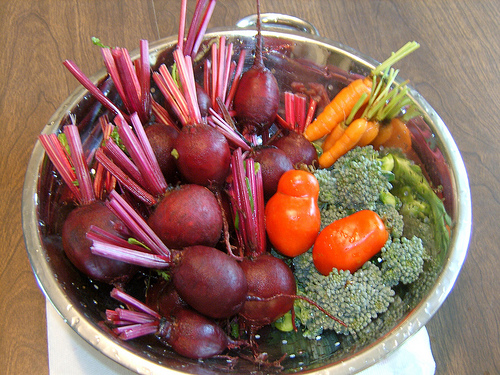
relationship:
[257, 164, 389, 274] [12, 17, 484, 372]
orange peppers are in bowl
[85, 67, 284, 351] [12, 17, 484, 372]
radishes are in bowl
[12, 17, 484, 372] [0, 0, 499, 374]
bowl on table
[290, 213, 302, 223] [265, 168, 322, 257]
water drops are on cherry tomato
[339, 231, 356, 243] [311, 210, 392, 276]
water drops are on orange peppers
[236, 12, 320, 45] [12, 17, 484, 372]
handle on bowl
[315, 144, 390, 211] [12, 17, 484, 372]
broccoli in bowl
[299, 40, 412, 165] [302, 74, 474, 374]
carrots in bowl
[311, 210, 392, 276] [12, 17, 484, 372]
orange peppers in bowl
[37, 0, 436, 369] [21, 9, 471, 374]
vegetable in pot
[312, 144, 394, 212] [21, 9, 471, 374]
broccoli in pot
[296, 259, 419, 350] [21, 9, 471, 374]
broccoli in pot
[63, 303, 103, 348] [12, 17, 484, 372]
water droplets on bowl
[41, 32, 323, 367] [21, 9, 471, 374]
vegetable in pot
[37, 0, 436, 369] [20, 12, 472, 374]
vegetable in bowl